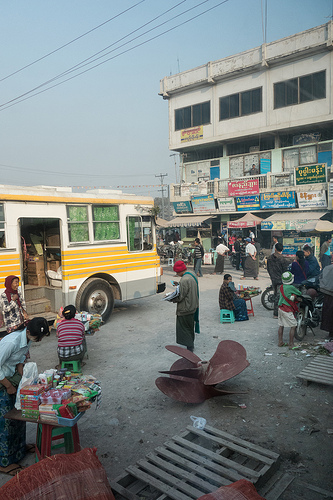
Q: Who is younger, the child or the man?
A: The child is younger than the man.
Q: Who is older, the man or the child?
A: The man is older than the child.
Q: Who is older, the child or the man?
A: The man is older than the child.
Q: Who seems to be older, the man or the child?
A: The man is older than the child.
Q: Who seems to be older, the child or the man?
A: The man is older than the child.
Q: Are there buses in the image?
A: Yes, there is a bus.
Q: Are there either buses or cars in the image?
A: Yes, there is a bus.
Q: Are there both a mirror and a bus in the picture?
A: No, there is a bus but no mirrors.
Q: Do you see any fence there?
A: No, there are no fences.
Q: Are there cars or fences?
A: No, there are no fences or cars.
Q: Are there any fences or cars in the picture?
A: No, there are no fences or cars.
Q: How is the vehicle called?
A: The vehicle is a bus.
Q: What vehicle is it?
A: The vehicle is a bus.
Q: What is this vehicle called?
A: This is a bus.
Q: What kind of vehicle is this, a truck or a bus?
A: This is a bus.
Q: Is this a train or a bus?
A: This is a bus.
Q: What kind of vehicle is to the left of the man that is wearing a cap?
A: The vehicle is a bus.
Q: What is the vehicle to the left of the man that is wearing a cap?
A: The vehicle is a bus.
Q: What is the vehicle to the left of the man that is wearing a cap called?
A: The vehicle is a bus.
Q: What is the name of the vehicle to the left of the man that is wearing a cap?
A: The vehicle is a bus.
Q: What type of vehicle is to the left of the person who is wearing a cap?
A: The vehicle is a bus.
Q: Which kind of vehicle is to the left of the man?
A: The vehicle is a bus.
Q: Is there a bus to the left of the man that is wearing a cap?
A: Yes, there is a bus to the left of the man.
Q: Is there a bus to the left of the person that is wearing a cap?
A: Yes, there is a bus to the left of the man.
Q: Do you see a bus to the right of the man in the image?
A: No, the bus is to the left of the man.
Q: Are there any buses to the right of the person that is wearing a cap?
A: No, the bus is to the left of the man.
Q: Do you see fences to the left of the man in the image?
A: No, there is a bus to the left of the man.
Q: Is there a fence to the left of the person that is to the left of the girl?
A: No, there is a bus to the left of the man.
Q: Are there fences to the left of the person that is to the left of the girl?
A: No, there is a bus to the left of the man.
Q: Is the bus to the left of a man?
A: Yes, the bus is to the left of a man.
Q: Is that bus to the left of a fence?
A: No, the bus is to the left of a man.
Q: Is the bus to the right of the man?
A: No, the bus is to the left of the man.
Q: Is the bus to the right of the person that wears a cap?
A: No, the bus is to the left of the man.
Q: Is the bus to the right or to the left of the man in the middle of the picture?
A: The bus is to the left of the man.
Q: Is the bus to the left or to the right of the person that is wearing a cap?
A: The bus is to the left of the man.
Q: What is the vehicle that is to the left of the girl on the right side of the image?
A: The vehicle is a bus.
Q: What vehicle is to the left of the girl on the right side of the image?
A: The vehicle is a bus.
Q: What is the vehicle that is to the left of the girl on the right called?
A: The vehicle is a bus.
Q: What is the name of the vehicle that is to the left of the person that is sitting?
A: The vehicle is a bus.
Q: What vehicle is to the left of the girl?
A: The vehicle is a bus.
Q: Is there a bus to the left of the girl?
A: Yes, there is a bus to the left of the girl.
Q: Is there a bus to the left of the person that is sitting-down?
A: Yes, there is a bus to the left of the girl.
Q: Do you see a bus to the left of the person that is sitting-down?
A: Yes, there is a bus to the left of the girl.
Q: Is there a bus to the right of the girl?
A: No, the bus is to the left of the girl.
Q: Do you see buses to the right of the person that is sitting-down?
A: No, the bus is to the left of the girl.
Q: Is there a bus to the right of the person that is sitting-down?
A: No, the bus is to the left of the girl.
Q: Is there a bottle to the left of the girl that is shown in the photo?
A: No, there is a bus to the left of the girl.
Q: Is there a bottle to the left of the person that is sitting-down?
A: No, there is a bus to the left of the girl.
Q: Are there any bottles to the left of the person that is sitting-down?
A: No, there is a bus to the left of the girl.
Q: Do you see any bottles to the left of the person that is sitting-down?
A: No, there is a bus to the left of the girl.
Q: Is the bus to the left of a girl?
A: Yes, the bus is to the left of a girl.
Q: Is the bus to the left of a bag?
A: No, the bus is to the left of a girl.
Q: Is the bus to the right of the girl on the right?
A: No, the bus is to the left of the girl.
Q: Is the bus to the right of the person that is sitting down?
A: No, the bus is to the left of the girl.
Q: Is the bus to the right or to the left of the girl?
A: The bus is to the left of the girl.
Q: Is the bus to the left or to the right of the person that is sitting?
A: The bus is to the left of the girl.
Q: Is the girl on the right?
A: Yes, the girl is on the right of the image.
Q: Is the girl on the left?
A: No, the girl is on the right of the image.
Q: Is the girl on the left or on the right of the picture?
A: The girl is on the right of the image.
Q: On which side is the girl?
A: The girl is on the right of the image.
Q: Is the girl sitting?
A: Yes, the girl is sitting.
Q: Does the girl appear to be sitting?
A: Yes, the girl is sitting.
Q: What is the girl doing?
A: The girl is sitting.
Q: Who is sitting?
A: The girl is sitting.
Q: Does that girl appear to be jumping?
A: No, the girl is sitting.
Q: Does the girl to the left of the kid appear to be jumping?
A: No, the girl is sitting.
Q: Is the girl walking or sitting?
A: The girl is sitting.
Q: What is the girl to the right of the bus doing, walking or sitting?
A: The girl is sitting.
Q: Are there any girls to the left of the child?
A: Yes, there is a girl to the left of the child.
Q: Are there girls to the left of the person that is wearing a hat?
A: Yes, there is a girl to the left of the child.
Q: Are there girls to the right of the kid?
A: No, the girl is to the left of the kid.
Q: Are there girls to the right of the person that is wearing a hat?
A: No, the girl is to the left of the kid.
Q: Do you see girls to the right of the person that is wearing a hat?
A: No, the girl is to the left of the kid.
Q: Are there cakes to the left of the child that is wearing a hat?
A: No, there is a girl to the left of the child.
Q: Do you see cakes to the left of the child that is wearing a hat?
A: No, there is a girl to the left of the child.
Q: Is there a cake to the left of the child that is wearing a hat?
A: No, there is a girl to the left of the child.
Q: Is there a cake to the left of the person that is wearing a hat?
A: No, there is a girl to the left of the child.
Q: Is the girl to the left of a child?
A: Yes, the girl is to the left of a child.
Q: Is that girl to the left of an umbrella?
A: No, the girl is to the left of a child.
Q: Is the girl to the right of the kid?
A: No, the girl is to the left of the kid.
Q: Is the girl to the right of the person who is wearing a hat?
A: No, the girl is to the left of the kid.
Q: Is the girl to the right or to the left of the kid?
A: The girl is to the left of the kid.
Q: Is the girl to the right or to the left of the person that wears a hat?
A: The girl is to the left of the kid.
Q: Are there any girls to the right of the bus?
A: Yes, there is a girl to the right of the bus.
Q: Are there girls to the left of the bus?
A: No, the girl is to the right of the bus.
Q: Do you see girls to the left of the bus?
A: No, the girl is to the right of the bus.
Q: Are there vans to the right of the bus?
A: No, there is a girl to the right of the bus.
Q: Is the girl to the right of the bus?
A: Yes, the girl is to the right of the bus.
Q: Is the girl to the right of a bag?
A: No, the girl is to the right of the bus.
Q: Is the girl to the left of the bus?
A: No, the girl is to the right of the bus.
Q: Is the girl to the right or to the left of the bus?
A: The girl is to the right of the bus.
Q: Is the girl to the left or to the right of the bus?
A: The girl is to the right of the bus.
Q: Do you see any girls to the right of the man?
A: Yes, there is a girl to the right of the man.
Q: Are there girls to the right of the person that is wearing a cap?
A: Yes, there is a girl to the right of the man.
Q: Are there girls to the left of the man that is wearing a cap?
A: No, the girl is to the right of the man.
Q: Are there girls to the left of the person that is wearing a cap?
A: No, the girl is to the right of the man.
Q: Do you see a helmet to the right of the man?
A: No, there is a girl to the right of the man.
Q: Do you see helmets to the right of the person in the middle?
A: No, there is a girl to the right of the man.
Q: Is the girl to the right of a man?
A: Yes, the girl is to the right of a man.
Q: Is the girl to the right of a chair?
A: No, the girl is to the right of a man.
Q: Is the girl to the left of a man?
A: No, the girl is to the right of a man.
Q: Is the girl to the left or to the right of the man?
A: The girl is to the right of the man.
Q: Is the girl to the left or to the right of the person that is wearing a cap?
A: The girl is to the right of the man.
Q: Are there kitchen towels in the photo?
A: No, there are no kitchen towels.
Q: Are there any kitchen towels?
A: No, there are no kitchen towels.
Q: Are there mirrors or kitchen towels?
A: No, there are no kitchen towels or mirrors.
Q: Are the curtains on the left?
A: Yes, the curtains are on the left of the image.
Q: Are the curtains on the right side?
A: No, the curtains are on the left of the image.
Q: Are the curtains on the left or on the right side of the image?
A: The curtains are on the left of the image.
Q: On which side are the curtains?
A: The curtains are on the left of the image.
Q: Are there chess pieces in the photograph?
A: No, there are no chess pieces.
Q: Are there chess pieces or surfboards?
A: No, there are no chess pieces or surfboards.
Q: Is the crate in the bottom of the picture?
A: Yes, the crate is in the bottom of the image.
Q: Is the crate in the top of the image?
A: No, the crate is in the bottom of the image.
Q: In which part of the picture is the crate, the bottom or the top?
A: The crate is in the bottom of the image.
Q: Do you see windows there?
A: Yes, there is a window.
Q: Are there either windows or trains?
A: Yes, there is a window.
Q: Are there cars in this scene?
A: No, there are no cars.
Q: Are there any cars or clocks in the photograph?
A: No, there are no cars or clocks.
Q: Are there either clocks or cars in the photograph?
A: No, there are no cars or clocks.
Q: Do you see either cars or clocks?
A: No, there are no cars or clocks.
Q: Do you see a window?
A: Yes, there is a window.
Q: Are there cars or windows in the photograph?
A: Yes, there is a window.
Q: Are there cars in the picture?
A: No, there are no cars.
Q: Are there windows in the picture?
A: Yes, there is a window.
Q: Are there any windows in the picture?
A: Yes, there is a window.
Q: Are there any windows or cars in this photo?
A: Yes, there is a window.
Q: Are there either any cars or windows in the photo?
A: Yes, there is a window.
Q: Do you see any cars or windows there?
A: Yes, there is a window.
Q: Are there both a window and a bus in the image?
A: Yes, there are both a window and a bus.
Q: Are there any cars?
A: No, there are no cars.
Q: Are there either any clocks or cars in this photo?
A: No, there are no cars or clocks.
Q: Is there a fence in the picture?
A: No, there are no fences.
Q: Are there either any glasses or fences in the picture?
A: No, there are no fences or glasses.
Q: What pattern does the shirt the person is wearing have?
A: The shirt has checkered pattern.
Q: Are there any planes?
A: No, there are no planes.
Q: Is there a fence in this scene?
A: No, there are no fences.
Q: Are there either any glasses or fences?
A: No, there are no fences or glasses.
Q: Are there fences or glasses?
A: No, there are no fences or glasses.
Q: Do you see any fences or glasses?
A: No, there are no fences or glasses.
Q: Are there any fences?
A: No, there are no fences.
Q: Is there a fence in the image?
A: No, there are no fences.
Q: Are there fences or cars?
A: No, there are no fences or cars.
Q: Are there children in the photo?
A: Yes, there is a child.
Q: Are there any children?
A: Yes, there is a child.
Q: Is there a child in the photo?
A: Yes, there is a child.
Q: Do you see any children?
A: Yes, there is a child.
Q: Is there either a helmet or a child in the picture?
A: Yes, there is a child.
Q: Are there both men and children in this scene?
A: Yes, there are both a child and a man.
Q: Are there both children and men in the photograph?
A: Yes, there are both a child and a man.